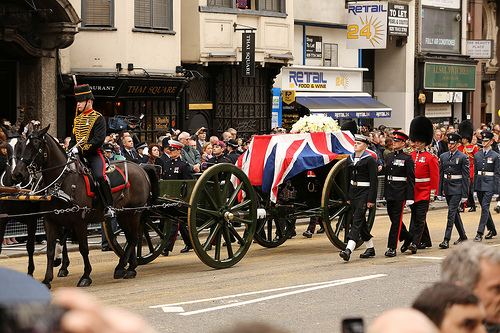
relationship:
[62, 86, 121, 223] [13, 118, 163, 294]
man on horse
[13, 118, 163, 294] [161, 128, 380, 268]
horse pulls wagon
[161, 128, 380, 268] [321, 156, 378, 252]
wagon has wheel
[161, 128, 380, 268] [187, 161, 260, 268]
wagon has wheel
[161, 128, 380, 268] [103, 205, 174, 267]
wagon has wheel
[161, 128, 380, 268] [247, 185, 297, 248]
wagon has wheel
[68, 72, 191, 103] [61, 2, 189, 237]
sign on restaurant